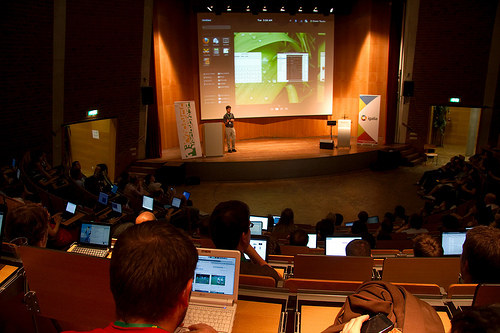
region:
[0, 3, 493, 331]
people watching a presentation in a darkened room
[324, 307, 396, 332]
a hand holding a cell phone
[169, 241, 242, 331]
images displayed on a computer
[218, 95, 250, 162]
man standing on a stage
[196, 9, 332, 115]
images and text on large screen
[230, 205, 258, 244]
person wearing glasses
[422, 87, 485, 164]
exit to outer area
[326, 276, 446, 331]
brown article of clothing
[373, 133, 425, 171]
steps leading up to stage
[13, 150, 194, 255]
many people in the audience have personal computers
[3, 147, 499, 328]
a group of people in a classroom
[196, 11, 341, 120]
a large screen on the back wall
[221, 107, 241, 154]
a teacher standing on the stage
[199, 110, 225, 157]
a podium on the side of the stage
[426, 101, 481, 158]
an exit to the classroom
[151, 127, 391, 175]
a stage in front of the classroom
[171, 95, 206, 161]
a sign on part of the stage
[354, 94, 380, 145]
another sign on the other side of the stage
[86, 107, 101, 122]
an exit sign above the door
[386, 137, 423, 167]
the stairs on the right side of the stage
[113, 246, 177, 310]
hair of a man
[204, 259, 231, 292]
monitor of a laptop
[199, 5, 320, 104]
projector on a wall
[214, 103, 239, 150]
a man before a forum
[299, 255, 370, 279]
part of a wooden board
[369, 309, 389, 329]
part of a black phone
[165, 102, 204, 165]
a standing white banner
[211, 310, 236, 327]
part of a white keyboard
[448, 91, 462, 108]
a white light at the entry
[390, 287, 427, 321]
part of a brown jacket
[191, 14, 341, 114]
Projector is on.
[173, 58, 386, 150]
Stage is brown color.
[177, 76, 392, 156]
One man is standing in the stage.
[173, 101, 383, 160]
Two advertisement panel is on both sides of stage.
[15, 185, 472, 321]
People are sitting in the bench.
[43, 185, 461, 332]
Laptops are in desk.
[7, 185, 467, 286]
Laptops are on.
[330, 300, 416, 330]
Mobile is on the brown coat.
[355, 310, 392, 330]
Mobile is black color.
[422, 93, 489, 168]
Entrance gate way.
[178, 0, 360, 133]
a very large projection screen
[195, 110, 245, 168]
a rectangular, white podium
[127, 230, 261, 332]
a bright white laptop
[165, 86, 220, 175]
a green and yellow sign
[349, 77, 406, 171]
a multi colored logo stand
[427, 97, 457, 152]
a green indoor plant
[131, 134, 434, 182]
a semi round stage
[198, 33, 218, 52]
the mozilla firefox logo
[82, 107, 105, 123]
a lit up exit sign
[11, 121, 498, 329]
auditorium seating in front of stage